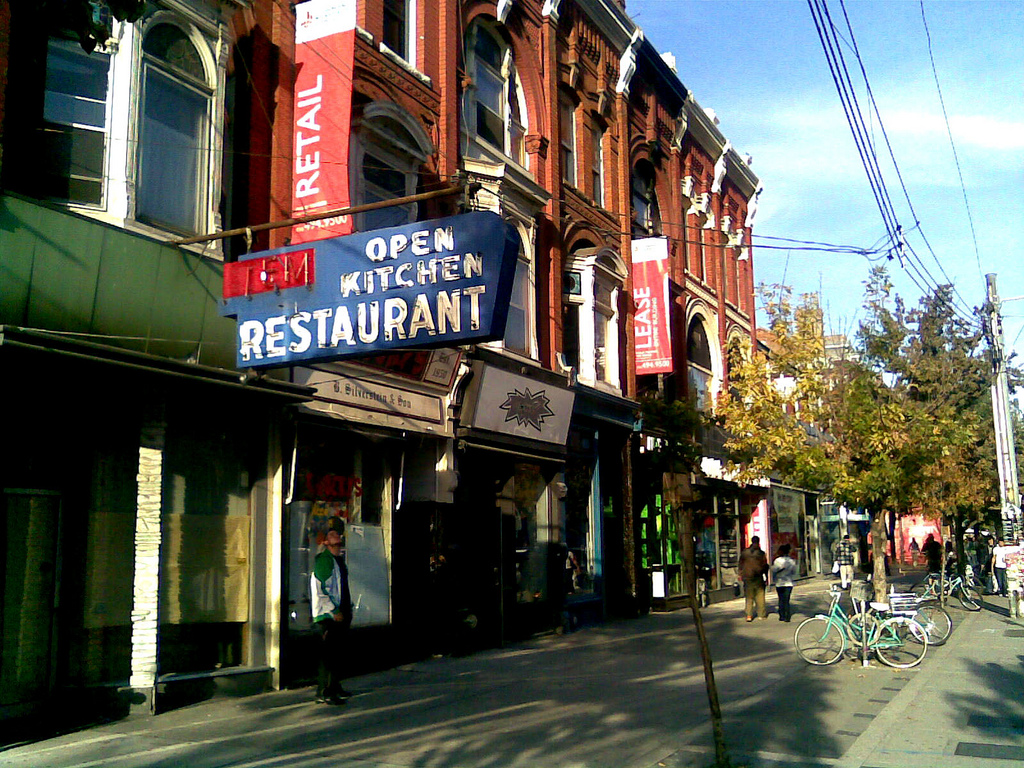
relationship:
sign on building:
[217, 210, 523, 368] [0, 9, 636, 746]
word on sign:
[229, 281, 489, 362] [234, 278, 490, 370]